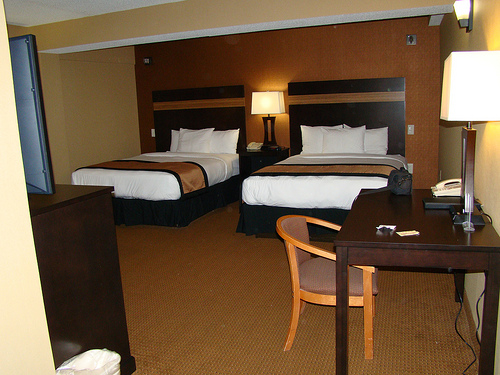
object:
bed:
[70, 84, 246, 228]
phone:
[428, 177, 465, 197]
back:
[9, 35, 56, 194]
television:
[6, 32, 59, 199]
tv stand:
[24, 181, 137, 374]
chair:
[275, 214, 381, 359]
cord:
[474, 286, 488, 350]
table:
[332, 186, 498, 375]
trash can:
[54, 345, 125, 374]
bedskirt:
[96, 173, 246, 229]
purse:
[388, 166, 414, 193]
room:
[0, 0, 499, 375]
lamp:
[248, 89, 284, 150]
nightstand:
[235, 148, 292, 216]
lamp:
[440, 48, 500, 228]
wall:
[438, 1, 499, 375]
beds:
[234, 75, 409, 243]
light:
[450, 0, 475, 26]